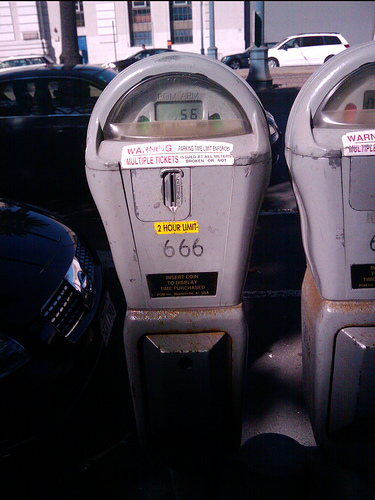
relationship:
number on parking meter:
[189, 233, 207, 256] [85, 47, 280, 489]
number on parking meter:
[176, 235, 191, 255] [85, 47, 280, 489]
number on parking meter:
[162, 237, 175, 257] [85, 47, 280, 489]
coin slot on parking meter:
[162, 164, 184, 213] [85, 47, 280, 489]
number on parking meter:
[187, 107, 200, 118] [85, 47, 280, 489]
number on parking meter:
[178, 106, 190, 120] [85, 47, 280, 489]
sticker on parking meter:
[152, 217, 197, 233] [85, 47, 280, 489]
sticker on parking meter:
[118, 155, 235, 167] [85, 47, 280, 489]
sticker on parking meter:
[118, 139, 233, 155] [85, 47, 280, 489]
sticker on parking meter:
[339, 129, 373, 143] [283, 39, 374, 498]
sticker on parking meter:
[341, 143, 373, 156] [283, 39, 374, 498]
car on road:
[268, 32, 352, 70] [231, 66, 323, 84]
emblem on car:
[72, 266, 92, 293] [0, 199, 114, 423]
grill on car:
[40, 251, 87, 340] [0, 199, 114, 423]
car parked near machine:
[3, 201, 105, 389] [84, 52, 276, 497]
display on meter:
[153, 102, 200, 121] [81, 51, 275, 491]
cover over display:
[103, 71, 251, 139] [159, 104, 199, 123]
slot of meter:
[162, 167, 185, 210] [81, 51, 275, 491]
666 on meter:
[163, 236, 206, 257] [81, 51, 275, 491]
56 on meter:
[177, 101, 202, 118] [81, 51, 275, 491]